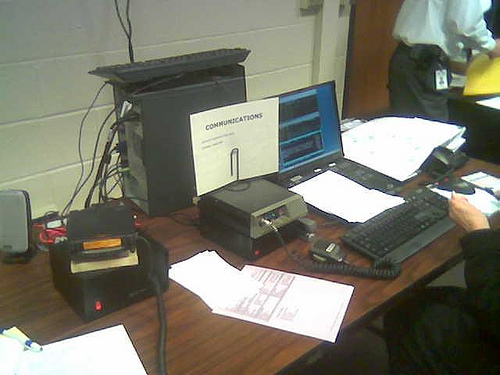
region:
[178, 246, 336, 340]
these are papers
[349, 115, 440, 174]
the paper is white in color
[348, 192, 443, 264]
this is a keyboard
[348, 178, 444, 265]
the key board is black in color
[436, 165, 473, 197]
this is a mouse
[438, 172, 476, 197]
the mouse is black in color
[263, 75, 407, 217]
this is a laptop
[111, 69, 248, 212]
this is central processing unit of a computer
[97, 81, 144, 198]
these are cables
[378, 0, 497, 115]
this is a person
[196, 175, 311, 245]
grey CB radio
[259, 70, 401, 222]
a black laptop with papers on top of it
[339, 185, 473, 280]
a black keyboard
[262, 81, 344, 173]
blue and black computer screen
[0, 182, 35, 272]
grey and black speaker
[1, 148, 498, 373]
a dark wood desk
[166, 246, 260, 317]
pile of white paper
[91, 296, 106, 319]
red on off switch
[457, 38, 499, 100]
yellow file folder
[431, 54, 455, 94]
white ID badge clipped to pants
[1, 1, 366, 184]
the wall behind the desk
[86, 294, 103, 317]
the red switch on the box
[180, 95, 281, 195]
a sign in front of the computer tower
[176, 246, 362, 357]
paperwork sitting on the desk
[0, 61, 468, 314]
assorted electronics sitting on the table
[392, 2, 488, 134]
a man standing over the desk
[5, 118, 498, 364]
the brown wooden desk everything is sitting on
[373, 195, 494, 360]
the man in black sitting at the desk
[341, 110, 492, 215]
more paperwork on the table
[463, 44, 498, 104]
the yellow folder on the table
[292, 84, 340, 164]
this is a laptop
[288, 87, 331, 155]
the laptop is on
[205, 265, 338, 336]
the papers are on the table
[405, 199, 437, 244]
this is a keyboard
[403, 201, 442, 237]
the keyboard is black in color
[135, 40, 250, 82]
a keyboard is on a monitor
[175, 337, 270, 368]
the table is wooden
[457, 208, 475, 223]
the hand is white in color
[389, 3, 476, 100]
the man is standing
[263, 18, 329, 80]
the wall is white in color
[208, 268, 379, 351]
square white paper on surface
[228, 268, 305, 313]
lines on white paper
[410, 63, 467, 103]
white badge on man's belt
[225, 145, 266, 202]
large paper holder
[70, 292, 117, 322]
red light on black electrical object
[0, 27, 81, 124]
lines on asphalt wall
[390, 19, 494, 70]
edge of long sleeve white shirt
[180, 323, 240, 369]
lines on dark brown surface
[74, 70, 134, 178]
long black electrical lines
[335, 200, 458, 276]
computer black keyboards